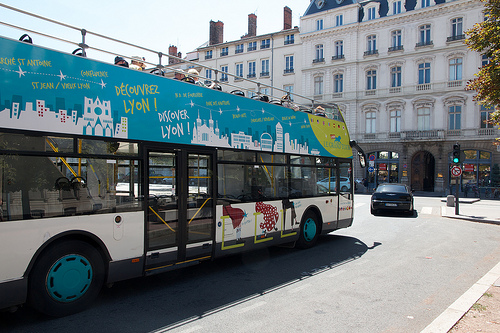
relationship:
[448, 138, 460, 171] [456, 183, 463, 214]
traffic light on pole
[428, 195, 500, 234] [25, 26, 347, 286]
sidewalk beside bus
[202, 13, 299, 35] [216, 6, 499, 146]
chimneys on top of buildng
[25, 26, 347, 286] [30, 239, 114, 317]
bus has wheel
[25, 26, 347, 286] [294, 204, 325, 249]
bus has front wheel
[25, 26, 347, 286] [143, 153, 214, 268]
bus has door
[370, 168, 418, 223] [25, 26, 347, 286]
car in front of bus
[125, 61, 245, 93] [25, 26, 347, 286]
people sitting on bus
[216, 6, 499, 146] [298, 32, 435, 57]
buildng has windows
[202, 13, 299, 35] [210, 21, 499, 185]
chimneys on top of building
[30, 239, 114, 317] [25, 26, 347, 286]
wheel on side of bus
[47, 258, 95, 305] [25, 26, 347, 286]
hubcap on bus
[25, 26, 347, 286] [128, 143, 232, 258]
bus has doors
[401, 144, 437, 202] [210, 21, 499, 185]
doorway on building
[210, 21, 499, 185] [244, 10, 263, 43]
building has chinmey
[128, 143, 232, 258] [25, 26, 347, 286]
doors on bus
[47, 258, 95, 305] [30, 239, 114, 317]
hubcap on wheel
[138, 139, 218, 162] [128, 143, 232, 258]
frame on edge of doors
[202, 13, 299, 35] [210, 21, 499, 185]
chimneys on building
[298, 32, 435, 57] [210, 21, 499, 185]
windows on building